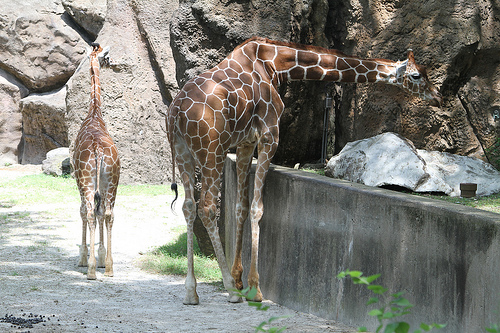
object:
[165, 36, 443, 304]
giraffe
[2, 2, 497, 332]
pen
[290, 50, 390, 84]
neck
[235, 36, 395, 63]
mane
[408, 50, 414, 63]
horn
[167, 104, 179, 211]
tail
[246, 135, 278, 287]
leg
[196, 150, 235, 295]
leg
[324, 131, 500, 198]
stone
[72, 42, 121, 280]
giraffe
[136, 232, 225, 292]
grass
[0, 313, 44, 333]
turds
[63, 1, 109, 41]
rock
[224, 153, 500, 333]
wall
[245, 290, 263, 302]
foot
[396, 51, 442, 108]
head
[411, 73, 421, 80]
eye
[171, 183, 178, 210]
hair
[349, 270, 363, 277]
leaf